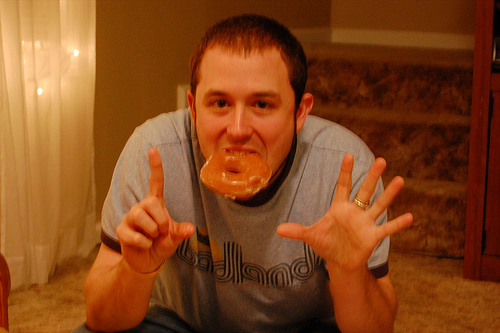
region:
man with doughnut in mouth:
[97, 11, 425, 325]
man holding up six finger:
[61, 23, 434, 328]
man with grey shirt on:
[90, 43, 429, 323]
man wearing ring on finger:
[107, 22, 417, 330]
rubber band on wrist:
[92, 185, 197, 304]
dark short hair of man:
[101, 16, 338, 187]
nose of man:
[210, 99, 257, 153]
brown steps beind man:
[252, 22, 454, 270]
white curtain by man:
[0, 34, 104, 306]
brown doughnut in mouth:
[185, 124, 269, 205]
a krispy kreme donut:
[204, 146, 283, 196]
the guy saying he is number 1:
[129, 137, 194, 227]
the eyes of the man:
[198, 83, 367, 143]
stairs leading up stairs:
[408, 61, 465, 204]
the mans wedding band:
[359, 186, 376, 215]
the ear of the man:
[177, 85, 204, 129]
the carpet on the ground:
[30, 282, 87, 318]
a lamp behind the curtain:
[13, 22, 88, 96]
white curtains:
[13, 33, 168, 235]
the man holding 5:
[303, 163, 430, 263]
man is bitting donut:
[132, 22, 336, 269]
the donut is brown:
[194, 143, 298, 221]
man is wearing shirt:
[73, 91, 370, 329]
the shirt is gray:
[76, 63, 428, 331]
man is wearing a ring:
[287, 158, 443, 331]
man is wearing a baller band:
[66, 187, 209, 319]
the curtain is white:
[4, 18, 146, 320]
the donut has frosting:
[175, 150, 300, 213]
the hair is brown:
[173, 16, 360, 131]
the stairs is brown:
[338, 48, 475, 288]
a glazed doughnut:
[196, 154, 271, 200]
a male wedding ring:
[352, 193, 369, 213]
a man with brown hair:
[169, 21, 332, 147]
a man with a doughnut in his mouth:
[174, 24, 323, 202]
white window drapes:
[3, 9, 106, 279]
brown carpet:
[327, 56, 474, 117]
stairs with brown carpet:
[315, 36, 475, 151]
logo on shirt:
[174, 250, 317, 292]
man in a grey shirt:
[81, 22, 424, 330]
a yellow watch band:
[115, 256, 175, 280]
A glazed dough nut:
[192, 137, 281, 209]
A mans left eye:
[245, 86, 285, 122]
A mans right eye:
[202, 84, 236, 115]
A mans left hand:
[283, 157, 404, 272]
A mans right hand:
[111, 156, 207, 274]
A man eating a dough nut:
[164, 29, 308, 226]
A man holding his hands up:
[104, 21, 453, 318]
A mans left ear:
[282, 82, 324, 136]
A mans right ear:
[180, 83, 196, 119]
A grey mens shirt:
[171, 216, 299, 309]